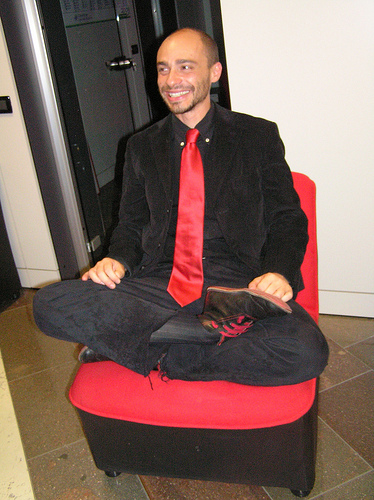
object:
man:
[32, 27, 329, 387]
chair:
[67, 170, 319, 498]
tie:
[166, 130, 205, 307]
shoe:
[196, 286, 292, 346]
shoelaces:
[211, 315, 253, 338]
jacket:
[103, 100, 309, 302]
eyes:
[180, 64, 194, 72]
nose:
[165, 68, 181, 88]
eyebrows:
[175, 58, 198, 65]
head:
[156, 27, 222, 115]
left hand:
[248, 272, 294, 303]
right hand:
[81, 257, 126, 290]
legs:
[33, 277, 196, 376]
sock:
[149, 313, 220, 346]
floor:
[1, 287, 372, 498]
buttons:
[180, 141, 184, 146]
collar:
[171, 98, 216, 146]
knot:
[182, 127, 198, 145]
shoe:
[78, 344, 160, 370]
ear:
[210, 62, 223, 83]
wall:
[0, 0, 372, 319]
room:
[1, 0, 372, 498]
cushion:
[68, 170, 317, 431]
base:
[72, 361, 321, 496]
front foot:
[291, 490, 310, 498]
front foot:
[106, 470, 121, 477]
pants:
[31, 272, 330, 386]